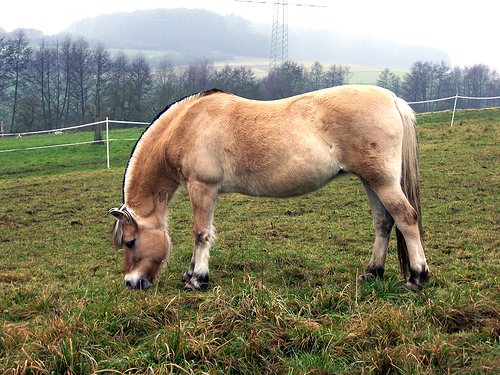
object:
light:
[247, 1, 392, 59]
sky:
[286, 9, 313, 27]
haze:
[75, 43, 115, 99]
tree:
[88, 57, 119, 106]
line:
[0, 119, 109, 137]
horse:
[107, 83, 434, 294]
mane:
[156, 89, 203, 122]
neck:
[121, 136, 182, 208]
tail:
[394, 96, 424, 283]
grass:
[10, 171, 98, 252]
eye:
[124, 237, 138, 248]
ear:
[107, 206, 139, 232]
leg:
[179, 182, 221, 294]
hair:
[131, 110, 163, 152]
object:
[268, 0, 290, 72]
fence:
[0, 115, 151, 169]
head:
[107, 203, 173, 294]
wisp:
[198, 279, 308, 360]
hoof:
[182, 273, 210, 293]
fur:
[224, 118, 277, 154]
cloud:
[120, 4, 241, 60]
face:
[120, 225, 153, 289]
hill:
[72, 10, 131, 47]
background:
[147, 18, 355, 74]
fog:
[144, 3, 354, 65]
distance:
[76, 28, 393, 186]